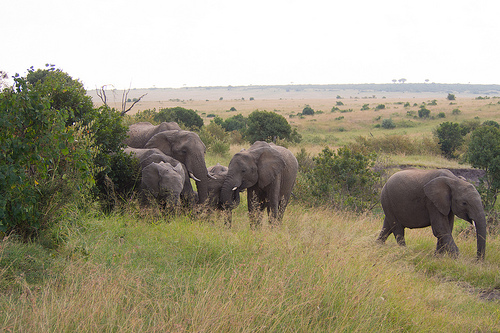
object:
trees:
[391, 78, 398, 84]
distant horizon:
[21, 72, 499, 89]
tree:
[92, 79, 149, 117]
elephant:
[375, 165, 493, 263]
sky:
[0, 1, 499, 94]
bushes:
[0, 62, 131, 249]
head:
[422, 174, 486, 225]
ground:
[5, 85, 497, 332]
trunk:
[471, 208, 489, 261]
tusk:
[471, 219, 477, 228]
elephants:
[218, 138, 302, 230]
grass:
[2, 82, 496, 332]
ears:
[420, 174, 463, 218]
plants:
[241, 107, 295, 146]